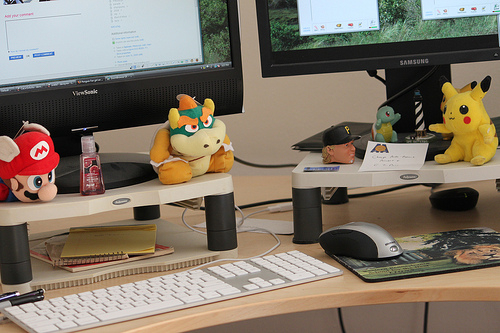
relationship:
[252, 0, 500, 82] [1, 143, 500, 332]
monitor on desk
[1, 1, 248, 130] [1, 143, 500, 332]
monitor on desk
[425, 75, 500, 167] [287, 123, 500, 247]
animal on stand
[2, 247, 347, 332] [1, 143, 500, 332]
keyboard on desk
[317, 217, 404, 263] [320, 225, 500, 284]
mouse on pad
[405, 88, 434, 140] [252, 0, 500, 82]
statue under monitor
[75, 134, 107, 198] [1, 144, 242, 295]
bottle on stand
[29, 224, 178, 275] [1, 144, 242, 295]
pads under stand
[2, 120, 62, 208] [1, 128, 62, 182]
toy with hat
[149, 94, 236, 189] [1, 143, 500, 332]
figure on desk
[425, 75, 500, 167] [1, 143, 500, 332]
animal on desk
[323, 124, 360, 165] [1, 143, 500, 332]
head on desk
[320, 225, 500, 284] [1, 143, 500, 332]
pad on desk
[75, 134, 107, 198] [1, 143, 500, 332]
bottle on desk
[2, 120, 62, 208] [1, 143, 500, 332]
toy on desk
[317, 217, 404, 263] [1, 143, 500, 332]
mouse on desk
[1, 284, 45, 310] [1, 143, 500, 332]
pens on desk